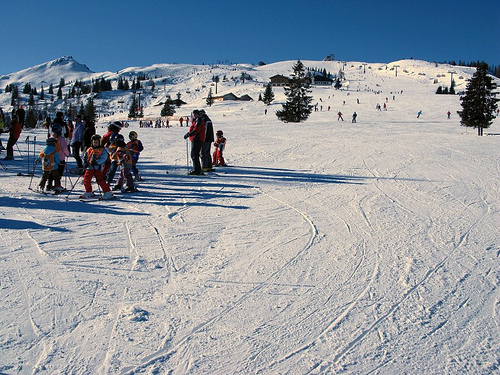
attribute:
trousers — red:
[83, 162, 105, 195]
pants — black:
[183, 141, 202, 177]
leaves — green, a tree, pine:
[454, 62, 496, 136]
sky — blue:
[28, 9, 444, 51]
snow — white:
[255, 171, 431, 342]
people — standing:
[6, 82, 235, 204]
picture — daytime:
[2, 39, 474, 352]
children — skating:
[76, 106, 149, 203]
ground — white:
[60, 187, 429, 335]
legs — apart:
[78, 165, 112, 205]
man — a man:
[182, 109, 204, 183]